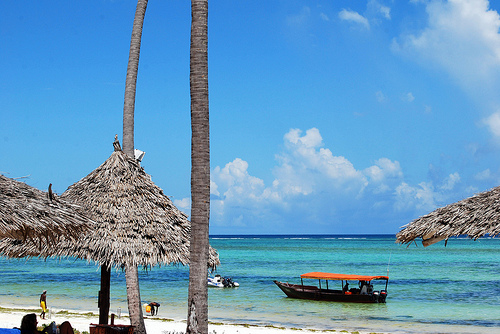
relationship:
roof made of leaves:
[0, 134, 220, 276] [65, 197, 149, 240]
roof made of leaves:
[42, 149, 221, 269] [81, 170, 188, 252]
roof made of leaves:
[0, 134, 220, 276] [68, 166, 167, 268]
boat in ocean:
[273, 270, 390, 303] [297, 227, 375, 254]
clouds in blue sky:
[172, 0, 499, 228] [1, 0, 498, 230]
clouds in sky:
[172, 0, 499, 228] [321, 48, 351, 63]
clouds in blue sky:
[172, 0, 499, 228] [1, 0, 497, 236]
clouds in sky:
[172, 0, 499, 228] [126, 44, 414, 227]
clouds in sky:
[172, 0, 499, 228] [1, 0, 499, 233]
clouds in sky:
[172, 0, 499, 228] [73, 27, 443, 219]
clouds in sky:
[172, 0, 499, 228] [97, 37, 456, 232]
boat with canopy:
[273, 270, 390, 303] [300, 271, 388, 281]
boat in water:
[176, 260, 243, 308] [254, 236, 425, 298]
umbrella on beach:
[0, 133, 221, 277] [2, 271, 484, 332]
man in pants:
[37, 287, 52, 321] [37, 299, 48, 313]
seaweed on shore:
[0, 304, 406, 332] [3, 265, 498, 330]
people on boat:
[330, 279, 369, 298] [261, 262, 401, 318]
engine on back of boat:
[213, 275, 243, 290] [188, 252, 264, 296]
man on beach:
[39, 290, 47, 320] [2, 288, 260, 330]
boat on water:
[273, 270, 390, 303] [0, 236, 496, 326]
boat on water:
[208, 276, 240, 287] [2, 222, 499, 323]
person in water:
[148, 302, 161, 317] [0, 236, 496, 326]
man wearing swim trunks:
[39, 290, 47, 320] [41, 299, 48, 313]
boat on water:
[271, 268, 393, 300] [5, 228, 497, 331]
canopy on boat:
[300, 269, 390, 281] [273, 272, 390, 305]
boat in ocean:
[273, 270, 390, 303] [3, 233, 493, 330]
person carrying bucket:
[145, 301, 162, 317] [145, 302, 152, 312]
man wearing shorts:
[39, 290, 47, 320] [35, 296, 56, 312]